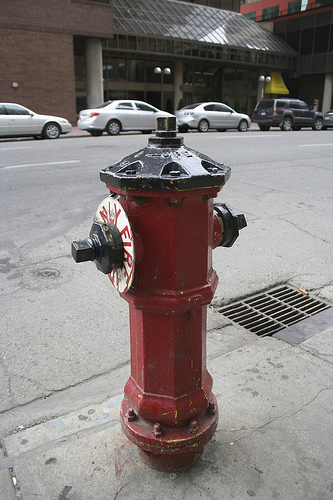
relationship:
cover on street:
[213, 282, 333, 339] [1, 131, 331, 500]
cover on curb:
[213, 282, 333, 339] [0, 283, 330, 498]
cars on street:
[1, 98, 331, 139] [1, 131, 331, 500]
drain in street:
[209, 282, 331, 338] [1, 131, 331, 500]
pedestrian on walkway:
[0, 119, 332, 141] [162, 96, 176, 110]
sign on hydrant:
[96, 195, 139, 294] [71, 116, 250, 471]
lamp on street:
[152, 65, 175, 110] [1, 131, 331, 500]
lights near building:
[151, 63, 172, 77] [1, 1, 297, 135]